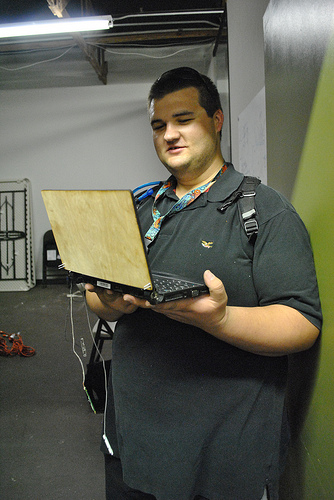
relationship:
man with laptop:
[84, 67, 321, 496] [42, 189, 211, 306]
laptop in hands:
[42, 189, 211, 306] [82, 271, 228, 329]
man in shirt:
[84, 67, 321, 496] [104, 163, 322, 499]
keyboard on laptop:
[150, 273, 210, 306] [42, 189, 211, 306]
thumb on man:
[203, 269, 226, 297] [84, 67, 321, 496]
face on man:
[150, 89, 214, 168] [84, 67, 321, 496]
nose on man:
[164, 122, 183, 144] [84, 67, 321, 496]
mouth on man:
[163, 145, 189, 153] [84, 67, 321, 496]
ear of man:
[211, 109, 225, 133] [84, 67, 321, 496]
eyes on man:
[152, 116, 195, 131] [84, 67, 321, 496]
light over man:
[1, 19, 115, 38] [84, 67, 321, 496]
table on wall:
[3, 179, 35, 295] [1, 48, 228, 165]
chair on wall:
[42, 229, 70, 287] [1, 48, 228, 165]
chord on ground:
[1, 332, 36, 359] [1, 284, 105, 486]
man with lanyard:
[84, 67, 321, 496] [138, 163, 229, 251]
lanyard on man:
[138, 163, 229, 251] [84, 67, 321, 496]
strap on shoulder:
[239, 172, 260, 241] [220, 162, 289, 220]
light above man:
[1, 19, 115, 38] [84, 67, 321, 496]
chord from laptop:
[68, 283, 115, 458] [42, 189, 211, 306]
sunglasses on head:
[154, 68, 216, 101] [144, 66, 224, 178]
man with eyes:
[84, 67, 321, 496] [152, 116, 195, 131]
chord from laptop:
[1, 332, 36, 359] [42, 189, 211, 306]